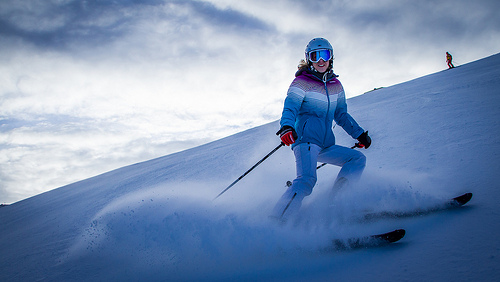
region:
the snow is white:
[424, 93, 482, 152]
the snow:
[410, 104, 460, 153]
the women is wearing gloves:
[276, 129, 298, 147]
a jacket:
[299, 78, 339, 144]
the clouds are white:
[35, 48, 167, 118]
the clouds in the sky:
[37, 55, 130, 115]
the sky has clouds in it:
[31, 51, 148, 131]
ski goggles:
[307, 48, 332, 61]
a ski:
[360, 225, 410, 243]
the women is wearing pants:
[298, 147, 316, 192]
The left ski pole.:
[210, 131, 276, 207]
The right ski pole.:
[280, 135, 361, 191]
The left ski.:
[246, 220, 401, 250]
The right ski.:
[315, 192, 470, 213]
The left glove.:
[277, 126, 294, 141]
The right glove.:
[355, 131, 365, 141]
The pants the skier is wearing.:
[270, 125, 360, 230]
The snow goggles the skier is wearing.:
[305, 47, 330, 59]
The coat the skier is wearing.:
[285, 72, 365, 142]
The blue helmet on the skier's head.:
[299, 35, 335, 54]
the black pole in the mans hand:
[207, 137, 278, 202]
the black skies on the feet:
[330, 188, 477, 252]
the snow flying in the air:
[303, 176, 455, 251]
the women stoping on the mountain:
[250, 29, 374, 236]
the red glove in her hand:
[275, 125, 297, 150]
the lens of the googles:
[308, 45, 332, 62]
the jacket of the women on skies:
[275, 72, 366, 146]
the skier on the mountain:
[435, 48, 467, 72]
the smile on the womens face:
[313, 59, 330, 70]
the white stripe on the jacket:
[290, 83, 347, 103]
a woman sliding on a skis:
[125, 30, 480, 277]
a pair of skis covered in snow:
[166, 179, 473, 254]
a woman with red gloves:
[271, 123, 299, 148]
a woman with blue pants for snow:
[257, 137, 373, 236]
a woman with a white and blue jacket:
[276, 59, 369, 154]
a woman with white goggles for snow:
[304, 48, 335, 62]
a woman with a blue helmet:
[302, 37, 333, 70]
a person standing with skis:
[439, 51, 462, 72]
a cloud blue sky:
[0, 0, 497, 211]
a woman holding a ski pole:
[155, 127, 297, 232]